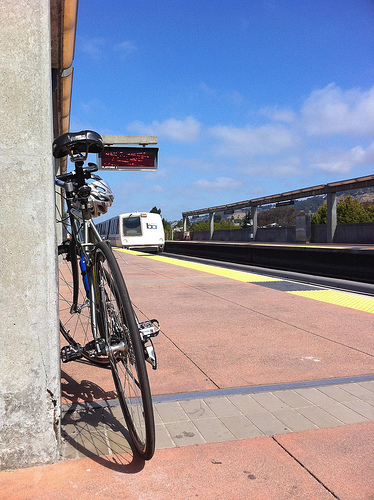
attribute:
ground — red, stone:
[113, 268, 332, 368]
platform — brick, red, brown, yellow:
[123, 238, 372, 484]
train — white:
[77, 196, 172, 257]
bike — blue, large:
[45, 115, 197, 469]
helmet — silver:
[51, 172, 131, 231]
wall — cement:
[5, 6, 57, 465]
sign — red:
[110, 136, 163, 166]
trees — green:
[192, 194, 373, 244]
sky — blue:
[145, 8, 291, 112]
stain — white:
[297, 346, 327, 368]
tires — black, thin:
[84, 250, 152, 454]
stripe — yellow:
[137, 259, 369, 330]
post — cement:
[44, 160, 74, 254]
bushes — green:
[177, 214, 243, 254]